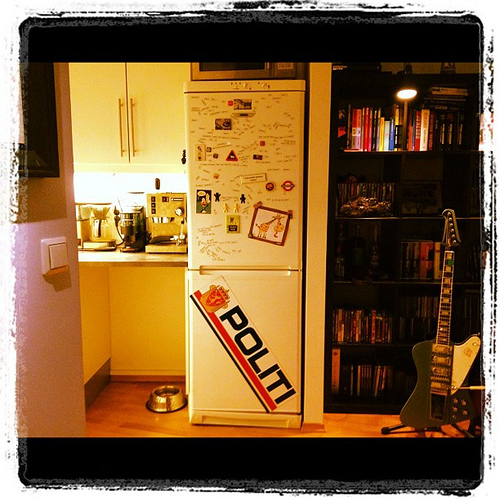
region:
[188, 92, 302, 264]
Magnets on the refrigerator.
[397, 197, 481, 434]
A green and white guitar.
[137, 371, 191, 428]
A silver dog bowl.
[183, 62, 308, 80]
The bottom of a silver microwave.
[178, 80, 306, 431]
A white refrigerator.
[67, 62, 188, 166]
White cabinets.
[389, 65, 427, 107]
A hanging light turned on.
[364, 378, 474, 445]
A back guitar stand.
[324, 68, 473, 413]
A bookcase full of items.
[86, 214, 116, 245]
A clear coffee pot.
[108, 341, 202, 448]
the bowl is silver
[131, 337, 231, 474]
the bowl is silver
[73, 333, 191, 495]
the bowl is silver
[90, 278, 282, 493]
the bowl is silver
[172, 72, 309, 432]
white fridge with magnets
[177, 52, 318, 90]
stainless steel microwave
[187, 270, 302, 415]
Italian "Police" magnet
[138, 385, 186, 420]
silver dog water bowl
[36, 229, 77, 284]
wall mounted thermastat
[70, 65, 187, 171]
light wooden kitchen cabinet door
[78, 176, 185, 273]
kitchen counter with small appliances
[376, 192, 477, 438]
green and white electric guitar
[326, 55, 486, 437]
book case with books and DVDs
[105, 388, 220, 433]
light colored hardwood floor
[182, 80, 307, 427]
a white two door referigerator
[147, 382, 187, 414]
a metal pet dish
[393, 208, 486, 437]
a standing guitar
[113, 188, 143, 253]
a drip coffe maker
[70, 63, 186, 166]
white overhead kitchen cabinets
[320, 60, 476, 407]
a tall black bookcase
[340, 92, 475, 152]
a shelf of books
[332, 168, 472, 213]
a shelf of books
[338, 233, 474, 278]
a shelf of books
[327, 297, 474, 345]
a shelf of books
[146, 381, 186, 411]
a gray dog food bowl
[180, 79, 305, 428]
a tall white refrigerator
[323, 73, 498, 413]
a tall black bookshelf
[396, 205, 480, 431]
a green and white guitar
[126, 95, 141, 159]
a long cabinet handle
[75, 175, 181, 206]
a reflection of light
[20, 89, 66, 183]
a part of a picture frame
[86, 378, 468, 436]
a brown hardwood floor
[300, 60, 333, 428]
part of a white wall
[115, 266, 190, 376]
a white cabinet